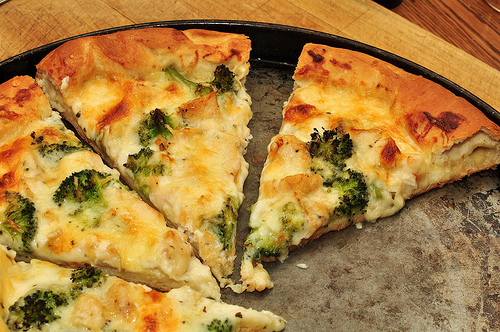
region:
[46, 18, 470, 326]
Pizza is in tray.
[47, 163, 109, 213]
Broccoli is green color.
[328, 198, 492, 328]
Tray is grey color.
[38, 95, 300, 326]
Four piece of pizza in plate.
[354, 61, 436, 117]
Bread is brown color.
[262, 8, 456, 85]
Tray is in wooden board.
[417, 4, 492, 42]
Table is brown color.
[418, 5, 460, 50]
Table is made of wood.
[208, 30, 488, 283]
Pizza piece is triangle in shape.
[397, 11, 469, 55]
wooden board is in table.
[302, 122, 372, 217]
broccoli on slice of pizza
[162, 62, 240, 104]
broccoli on slice of pizza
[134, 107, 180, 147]
broccoli on slice of pizza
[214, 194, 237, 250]
broccoli on slice of pizza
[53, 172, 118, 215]
broccoli on slice of pizza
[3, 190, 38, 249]
broccoli on slice of pizza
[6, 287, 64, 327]
broccoli on slice of pizza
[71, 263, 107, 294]
broccoli on slice of pizza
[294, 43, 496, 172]
crust on slice of pizza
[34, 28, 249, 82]
crust on slice of pizza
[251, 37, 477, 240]
slice of pizza on a pan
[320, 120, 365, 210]
broccoli on a pizza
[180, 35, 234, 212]
slice of pizza on a pan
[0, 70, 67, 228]
slice of pizza on pan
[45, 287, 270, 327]
slice of pizza on a pan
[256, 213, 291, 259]
broccoli on a pizza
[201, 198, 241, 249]
broccoli on a pizza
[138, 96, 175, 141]
broccoli on a pizza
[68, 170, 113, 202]
broccoli on a pizza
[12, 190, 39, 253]
broccoli on a pizza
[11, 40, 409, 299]
Pizza is in plate.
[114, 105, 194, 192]
Broccoli is green color.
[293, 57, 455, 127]
bread is brown color.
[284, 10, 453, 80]
Tray is in the wooden board.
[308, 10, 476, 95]
Board is brown color.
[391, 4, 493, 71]
Board is in the table.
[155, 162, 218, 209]
Cheese is white color.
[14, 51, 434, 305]
pizza in the photo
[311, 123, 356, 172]
green topping on pizza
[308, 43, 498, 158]
crust on the pizza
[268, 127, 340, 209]
cheese on the pizza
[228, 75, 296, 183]
space in between the pizzas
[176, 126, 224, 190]
cheese on the pizza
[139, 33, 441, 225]
two pieces of pizza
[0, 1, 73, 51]
table under the pizza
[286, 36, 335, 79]
edge of the crust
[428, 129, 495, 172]
side of the pizza